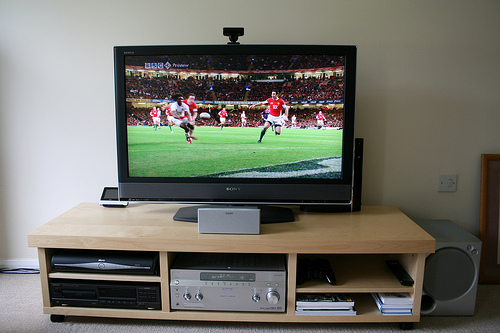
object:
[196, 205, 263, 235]
speaker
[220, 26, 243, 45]
sensor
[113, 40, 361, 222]
television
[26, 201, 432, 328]
entertainment center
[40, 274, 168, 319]
console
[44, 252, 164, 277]
box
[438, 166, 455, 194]
socket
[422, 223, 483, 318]
speaker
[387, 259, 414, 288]
black remote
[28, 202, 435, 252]
counter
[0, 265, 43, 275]
power cords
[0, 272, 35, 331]
floor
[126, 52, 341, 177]
screen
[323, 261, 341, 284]
remote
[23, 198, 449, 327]
shelf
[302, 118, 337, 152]
ground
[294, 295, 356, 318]
cases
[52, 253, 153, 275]
dvd player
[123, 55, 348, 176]
soccer match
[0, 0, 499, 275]
wall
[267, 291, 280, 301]
knob